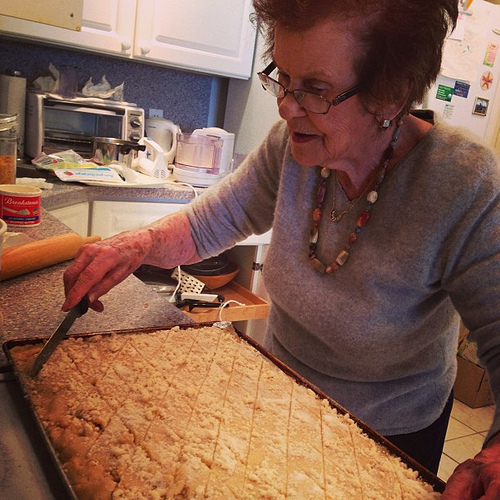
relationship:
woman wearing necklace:
[62, 1, 496, 498] [302, 190, 325, 273]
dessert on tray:
[108, 372, 228, 472] [2, 317, 447, 498]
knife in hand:
[27, 291, 93, 375] [59, 226, 151, 313]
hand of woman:
[59, 236, 147, 309] [62, 1, 496, 498]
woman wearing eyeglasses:
[62, 1, 496, 498] [256, 60, 374, 114]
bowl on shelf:
[185, 264, 244, 290] [163, 285, 273, 322]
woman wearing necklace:
[62, 1, 496, 498] [307, 112, 409, 274]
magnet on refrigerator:
[452, 80, 472, 98] [419, 67, 495, 142]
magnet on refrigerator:
[436, 86, 455, 101] [419, 67, 495, 142]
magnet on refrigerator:
[480, 72, 492, 89] [419, 67, 495, 142]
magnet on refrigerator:
[440, 104, 454, 119] [419, 67, 495, 142]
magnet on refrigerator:
[470, 97, 491, 118] [419, 67, 495, 142]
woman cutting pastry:
[62, 1, 500, 497] [22, 345, 424, 497]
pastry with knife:
[22, 345, 424, 497] [22, 295, 102, 377]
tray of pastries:
[2, 317, 447, 498] [31, 302, 445, 498]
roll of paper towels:
[3, 69, 27, 159] [2, 71, 27, 158]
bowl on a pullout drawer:
[180, 259, 241, 290] [143, 272, 277, 323]